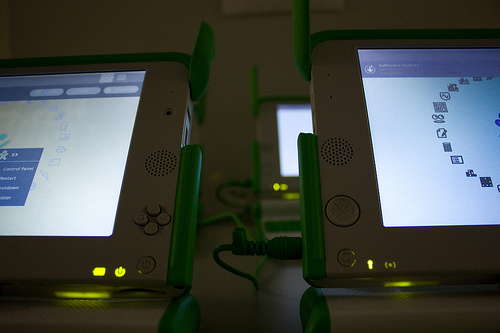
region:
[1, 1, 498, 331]
several laptops in rows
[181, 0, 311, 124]
laptop antenna are green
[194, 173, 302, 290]
charge cable cord jacks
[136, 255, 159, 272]
the power button is circular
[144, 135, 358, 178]
speakers are beside screens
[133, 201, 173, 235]
four way section of buttons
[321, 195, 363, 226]
four way directional pad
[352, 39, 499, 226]
screen on right computer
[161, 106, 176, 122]
webcam hole is black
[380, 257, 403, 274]
Green light on machine.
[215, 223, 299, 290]
Green cord on electronics.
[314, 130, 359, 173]
Speaker on the electronics.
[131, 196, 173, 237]
four buttons on the electronic.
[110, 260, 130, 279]
Power button on the electronic.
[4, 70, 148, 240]
Screen on the electronic device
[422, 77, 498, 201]
Images on the screen.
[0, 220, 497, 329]
White desk in the forefront.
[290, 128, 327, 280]
Green bar on the electronic device.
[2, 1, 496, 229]
White wall in the background.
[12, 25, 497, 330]
game systems on a table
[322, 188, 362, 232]
button on a system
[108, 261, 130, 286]
apple logo on a system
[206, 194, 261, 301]
green wires on a table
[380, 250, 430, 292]
green power button light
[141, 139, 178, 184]
speaker on a system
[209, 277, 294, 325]
table where gaming system is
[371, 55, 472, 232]
illuminated screen on a system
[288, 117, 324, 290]
green side bar of a system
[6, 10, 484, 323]
three illuminated systems on a table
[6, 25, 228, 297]
A lit up computer monitor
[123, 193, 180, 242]
Four control buttons on a computer monitor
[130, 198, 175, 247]
A group of control buttons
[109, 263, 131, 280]
A green power light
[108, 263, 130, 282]
A green power indicator on a monitor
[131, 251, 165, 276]
A power button on a computer monitor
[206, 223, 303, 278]
A computer power cord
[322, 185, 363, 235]
A large power button on a computer monitor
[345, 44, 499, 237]
A computer monitor screen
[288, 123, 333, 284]
A green plastic attachment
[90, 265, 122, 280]
the lights are yellow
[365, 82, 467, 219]
screen on the wall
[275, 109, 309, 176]
screen on the wall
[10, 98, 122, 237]
screen on the wall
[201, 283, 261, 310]
the desk is wood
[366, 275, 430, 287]
glow from the screen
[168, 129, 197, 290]
this part is green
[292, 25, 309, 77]
this part is screen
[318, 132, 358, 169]
speaker on the computer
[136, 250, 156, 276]
button on the computer